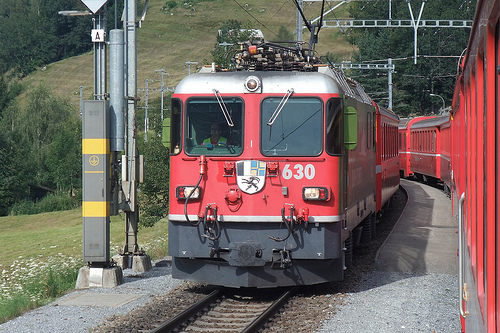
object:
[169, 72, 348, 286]
front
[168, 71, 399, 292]
train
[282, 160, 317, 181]
630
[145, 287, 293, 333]
tracks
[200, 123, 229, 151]
driver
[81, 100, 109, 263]
box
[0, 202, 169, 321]
grass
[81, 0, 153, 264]
poles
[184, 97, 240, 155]
window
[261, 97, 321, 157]
window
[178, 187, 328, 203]
lights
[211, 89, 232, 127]
windshield wiper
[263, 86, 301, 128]
windshield wiper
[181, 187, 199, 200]
headlight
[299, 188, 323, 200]
headlight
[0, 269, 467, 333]
gravel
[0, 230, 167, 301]
flowers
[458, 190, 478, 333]
hand rail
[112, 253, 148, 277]
base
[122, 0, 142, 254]
support beam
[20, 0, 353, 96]
grass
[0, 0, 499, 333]
background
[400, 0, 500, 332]
train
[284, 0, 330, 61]
cable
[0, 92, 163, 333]
side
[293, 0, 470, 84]
rods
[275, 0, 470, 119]
top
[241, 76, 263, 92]
light indicator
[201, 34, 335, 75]
stuff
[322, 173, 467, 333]
pavement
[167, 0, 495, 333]
trains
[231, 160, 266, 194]
crest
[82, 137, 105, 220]
stripes